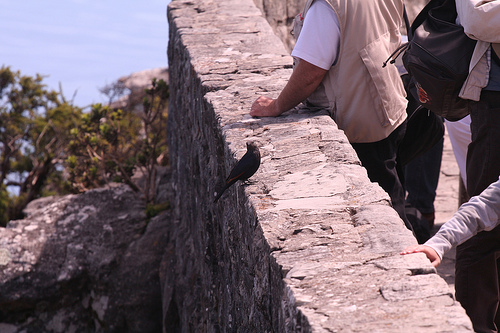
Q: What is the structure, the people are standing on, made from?
A: Stone.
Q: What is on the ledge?
A: A bird.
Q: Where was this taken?
A: On a stone building.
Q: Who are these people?
A: Tourists.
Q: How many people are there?
A: Four.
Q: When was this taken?
A: During the day.